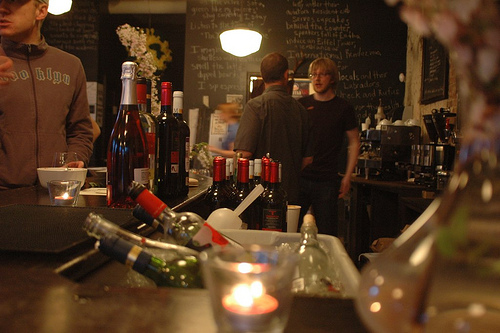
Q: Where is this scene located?
A: Bar.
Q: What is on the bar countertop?
A: Wine bottles.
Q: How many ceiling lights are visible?
A: Two.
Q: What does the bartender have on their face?
A: Glasses.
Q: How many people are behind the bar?
A: 2.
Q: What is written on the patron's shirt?
A: Brooklyn.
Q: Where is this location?
A: Bar.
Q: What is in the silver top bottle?
A: Wine.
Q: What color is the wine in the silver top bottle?
A: Red.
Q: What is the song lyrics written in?
A: Chalk.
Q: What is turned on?
A: Lights.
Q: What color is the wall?
A: Black.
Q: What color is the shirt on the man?
A: Black.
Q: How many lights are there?
A: Two.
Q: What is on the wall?
A: Writing.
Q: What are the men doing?
A: Talking.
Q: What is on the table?
A: Wine bottles.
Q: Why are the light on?
A: Dark.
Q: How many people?
A: Four.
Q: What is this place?
A: Bar.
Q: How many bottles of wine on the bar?
A: Four.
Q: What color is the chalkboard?
A: Black.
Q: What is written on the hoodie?
A: Brooklyn.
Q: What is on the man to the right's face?
A: Glasses.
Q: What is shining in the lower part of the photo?
A: Candle.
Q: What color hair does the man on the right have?
A: Blonde.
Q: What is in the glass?
A: Candle.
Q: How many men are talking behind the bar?
A: Two.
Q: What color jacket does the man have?
A: Brown.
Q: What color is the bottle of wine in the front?
A: Green.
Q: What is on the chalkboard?
A: Writing.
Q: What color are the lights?
A: White.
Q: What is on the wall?
A: Writing.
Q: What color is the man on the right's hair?
A: Blonde.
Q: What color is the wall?
A: Black.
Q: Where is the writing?
A: On the walls.